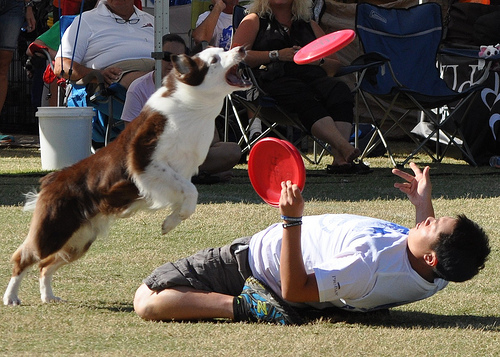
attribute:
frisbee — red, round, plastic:
[290, 21, 360, 71]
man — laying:
[124, 193, 493, 333]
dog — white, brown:
[11, 33, 251, 285]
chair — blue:
[352, 3, 480, 165]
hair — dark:
[449, 235, 481, 265]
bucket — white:
[34, 100, 95, 169]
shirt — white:
[256, 211, 411, 311]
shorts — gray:
[138, 228, 248, 304]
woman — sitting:
[240, 2, 378, 172]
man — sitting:
[58, 1, 156, 75]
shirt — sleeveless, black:
[248, 16, 333, 79]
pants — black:
[271, 68, 361, 125]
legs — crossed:
[301, 77, 393, 171]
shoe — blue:
[227, 278, 302, 332]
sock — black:
[225, 294, 250, 324]